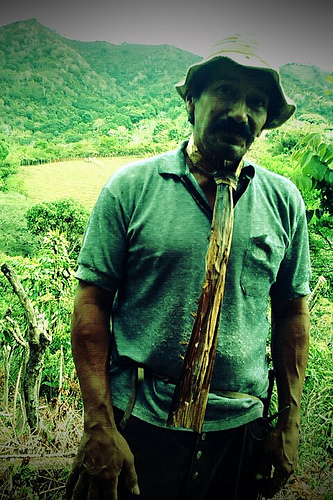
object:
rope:
[120, 368, 260, 430]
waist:
[110, 361, 267, 420]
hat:
[174, 33, 296, 130]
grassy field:
[18, 154, 152, 206]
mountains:
[0, 17, 332, 152]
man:
[64, 31, 310, 498]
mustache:
[202, 118, 254, 159]